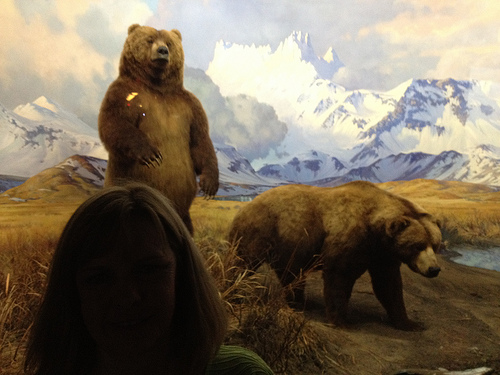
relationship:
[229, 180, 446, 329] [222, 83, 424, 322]
bear walking background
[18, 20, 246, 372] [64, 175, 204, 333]
bear behind woman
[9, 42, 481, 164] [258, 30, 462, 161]
mountains in distance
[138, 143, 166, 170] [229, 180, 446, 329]
paw on bear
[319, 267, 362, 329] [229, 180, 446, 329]
leg on bear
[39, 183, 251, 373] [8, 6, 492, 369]
woman posing for photograph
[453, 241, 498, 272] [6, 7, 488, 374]
water in background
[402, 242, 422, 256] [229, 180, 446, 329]
eye on bear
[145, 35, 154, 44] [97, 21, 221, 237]
eye on bear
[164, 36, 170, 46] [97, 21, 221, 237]
eye on bear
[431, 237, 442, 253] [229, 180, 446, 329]
eye on bear